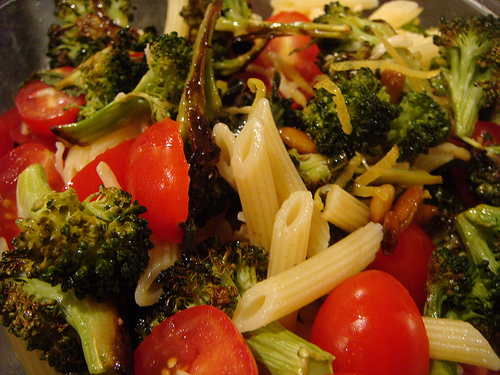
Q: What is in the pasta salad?
A: Tomato, beans, and broccoli.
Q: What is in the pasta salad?
A: Tomato, cheese, broccoli, beans, and dressing.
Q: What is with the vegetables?
A: Cooked pasta.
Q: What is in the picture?
A: Pasta.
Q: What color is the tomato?
A: Red.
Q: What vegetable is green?
A: Broccoli.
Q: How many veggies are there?
A: 2.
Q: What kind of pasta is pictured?
A: Penne pasta.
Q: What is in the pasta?
A: Noodles and vegetables.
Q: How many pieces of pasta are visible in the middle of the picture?
A: 4.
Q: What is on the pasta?
A: Oil.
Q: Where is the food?
A: In a bowl.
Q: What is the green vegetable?
A: Broccoli.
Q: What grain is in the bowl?
A: Noodles.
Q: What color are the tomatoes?
A: Red.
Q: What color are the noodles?
A: White.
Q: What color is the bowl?
A: Black.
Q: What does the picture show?
A: Food.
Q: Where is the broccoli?
A: Mixed in with the other food.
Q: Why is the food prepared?
A: To be eaten.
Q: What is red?
A: Tomatoes.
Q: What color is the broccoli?
A: Green.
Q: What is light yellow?
A: The macaroni.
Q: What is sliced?
A: Tomatoes.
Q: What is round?
A: A tomato in the front.